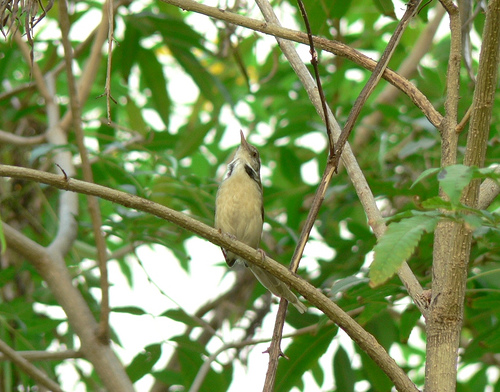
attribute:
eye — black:
[244, 148, 266, 158]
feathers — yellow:
[221, 179, 259, 233]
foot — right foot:
[237, 251, 315, 285]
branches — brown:
[228, 20, 420, 204]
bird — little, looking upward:
[178, 98, 302, 279]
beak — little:
[239, 130, 246, 145]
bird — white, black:
[215, 127, 265, 266]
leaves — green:
[126, 23, 216, 188]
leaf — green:
[135, 45, 175, 130]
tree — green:
[2, 2, 497, 389]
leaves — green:
[263, 87, 484, 294]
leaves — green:
[133, 36, 315, 235]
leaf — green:
[271, 111, 300, 166]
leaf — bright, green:
[356, 302, 401, 389]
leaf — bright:
[364, 212, 461, 287]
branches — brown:
[1, 1, 49, 34]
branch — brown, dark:
[258, 2, 428, 389]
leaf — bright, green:
[367, 213, 443, 285]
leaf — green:
[365, 209, 427, 289]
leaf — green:
[269, 324, 338, 389]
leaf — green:
[438, 163, 473, 211]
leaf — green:
[138, 15, 206, 47]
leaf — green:
[225, 33, 266, 105]